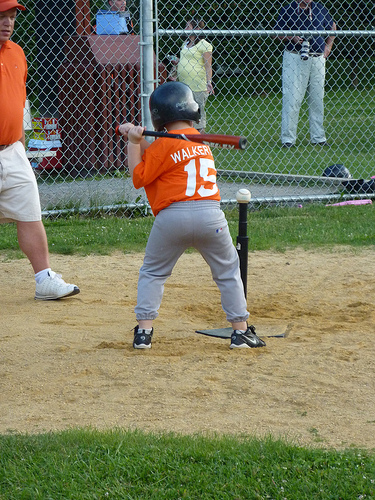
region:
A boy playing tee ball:
[107, 75, 320, 358]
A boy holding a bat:
[118, 74, 254, 166]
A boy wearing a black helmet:
[109, 73, 231, 176]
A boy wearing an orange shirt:
[112, 78, 232, 214]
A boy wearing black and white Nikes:
[125, 311, 273, 357]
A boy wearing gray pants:
[124, 195, 265, 310]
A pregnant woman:
[166, 12, 230, 115]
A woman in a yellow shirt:
[172, 17, 218, 93]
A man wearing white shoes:
[13, 227, 88, 307]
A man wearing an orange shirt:
[4, 3, 42, 156]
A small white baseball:
[237, 184, 255, 208]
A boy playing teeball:
[102, 64, 345, 445]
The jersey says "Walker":
[169, 135, 223, 169]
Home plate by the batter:
[199, 306, 293, 345]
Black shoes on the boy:
[226, 320, 267, 351]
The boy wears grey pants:
[140, 199, 252, 323]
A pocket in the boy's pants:
[206, 215, 226, 235]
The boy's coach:
[0, 0, 95, 296]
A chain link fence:
[41, 0, 363, 180]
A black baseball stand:
[229, 188, 284, 325]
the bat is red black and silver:
[181, 129, 237, 153]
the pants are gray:
[173, 219, 216, 251]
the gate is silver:
[226, 49, 267, 95]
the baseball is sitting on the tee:
[231, 182, 256, 207]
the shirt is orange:
[4, 60, 17, 95]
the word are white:
[165, 147, 221, 182]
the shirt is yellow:
[185, 56, 200, 80]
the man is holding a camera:
[293, 24, 318, 68]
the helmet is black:
[159, 88, 183, 108]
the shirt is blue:
[298, 19, 316, 38]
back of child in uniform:
[109, 70, 264, 353]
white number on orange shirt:
[177, 157, 223, 210]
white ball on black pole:
[233, 184, 258, 221]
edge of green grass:
[197, 421, 291, 463]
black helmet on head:
[143, 77, 208, 133]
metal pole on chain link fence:
[342, 28, 369, 89]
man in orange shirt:
[1, 9, 33, 155]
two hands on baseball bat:
[112, 120, 245, 154]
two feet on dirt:
[120, 318, 285, 365]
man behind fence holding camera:
[270, 6, 341, 89]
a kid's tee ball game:
[4, 10, 374, 417]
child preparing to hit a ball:
[108, 79, 264, 360]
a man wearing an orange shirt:
[1, 2, 71, 304]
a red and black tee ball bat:
[116, 115, 253, 152]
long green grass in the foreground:
[4, 431, 372, 492]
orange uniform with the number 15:
[141, 136, 219, 199]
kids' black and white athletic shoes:
[124, 318, 267, 353]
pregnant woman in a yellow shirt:
[172, 15, 226, 130]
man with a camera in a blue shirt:
[271, 1, 339, 149]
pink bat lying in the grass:
[319, 196, 374, 210]